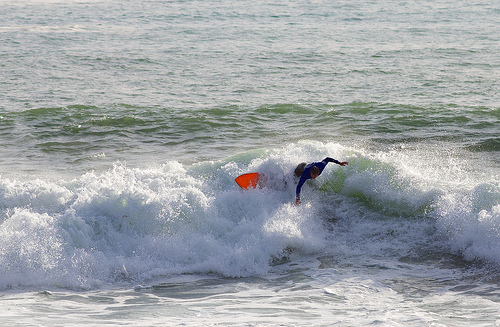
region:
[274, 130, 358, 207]
This is a person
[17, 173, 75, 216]
A portion of the ocean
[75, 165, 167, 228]
A portion of the ocean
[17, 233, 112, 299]
A portion of the ocean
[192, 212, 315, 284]
A portion of the ocean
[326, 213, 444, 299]
A portion of the ocean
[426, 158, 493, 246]
A portion of the ocean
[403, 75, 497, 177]
A portion of the ocean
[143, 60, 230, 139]
A portion of the ocean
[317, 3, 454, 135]
A portion of the ocean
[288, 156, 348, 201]
man riding on surfboard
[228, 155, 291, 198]
surfboard is red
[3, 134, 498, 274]
wave is big and white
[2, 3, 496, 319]
ocean behind wave is calm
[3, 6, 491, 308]
ocean is blue and green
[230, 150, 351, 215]
surfer is almost falling off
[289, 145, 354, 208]
man wearing wetsuit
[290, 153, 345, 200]
wetsuit is blue and black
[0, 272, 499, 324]
foam in ocean from crashing waves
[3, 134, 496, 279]
wave is crashing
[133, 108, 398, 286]
a man is surfing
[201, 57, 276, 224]
the surfboard is red in colour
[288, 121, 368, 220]
his arms are stretched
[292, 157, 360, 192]
the sweater is blue in colour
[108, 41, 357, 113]
the water is calm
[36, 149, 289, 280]
the wave is white in colour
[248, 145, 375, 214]
his is facing downward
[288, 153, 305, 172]
the short is brown in colour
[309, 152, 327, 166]
the sweater has a white logo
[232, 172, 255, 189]
A large red surfboard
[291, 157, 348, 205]
A person in the ocean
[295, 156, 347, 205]
A person surfing on the ocean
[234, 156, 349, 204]
A person in the ocean on a surfboard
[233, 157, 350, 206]
A person riding a red surfboard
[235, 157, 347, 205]
A person using a surfboard in the water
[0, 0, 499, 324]
A large expanse of water with a surfer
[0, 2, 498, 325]
The ocean with a person surfing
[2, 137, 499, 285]
Rolling ocean waves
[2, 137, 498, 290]
Ocean waves with a surfer on a red board